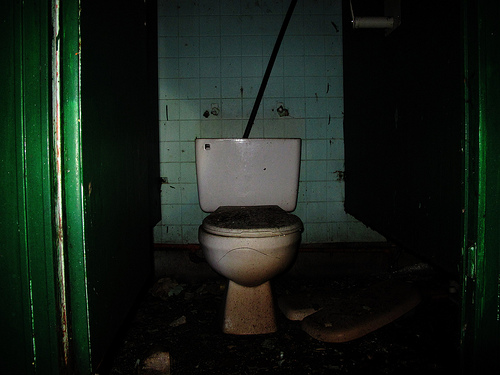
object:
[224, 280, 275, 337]
base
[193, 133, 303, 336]
toilet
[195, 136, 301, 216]
tank lid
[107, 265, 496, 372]
floor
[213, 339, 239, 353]
dirt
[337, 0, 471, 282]
structure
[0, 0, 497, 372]
bathroom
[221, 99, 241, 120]
tile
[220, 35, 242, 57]
tile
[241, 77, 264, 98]
tile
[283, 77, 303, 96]
tile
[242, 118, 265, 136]
tile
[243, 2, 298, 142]
pole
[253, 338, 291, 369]
trash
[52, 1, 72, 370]
metal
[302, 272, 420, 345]
lid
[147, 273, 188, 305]
garbage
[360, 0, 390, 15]
hole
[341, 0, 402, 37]
handle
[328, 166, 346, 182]
marks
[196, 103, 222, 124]
marks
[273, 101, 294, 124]
marks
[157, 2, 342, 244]
wall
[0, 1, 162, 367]
structure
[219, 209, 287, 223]
something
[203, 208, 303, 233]
seat